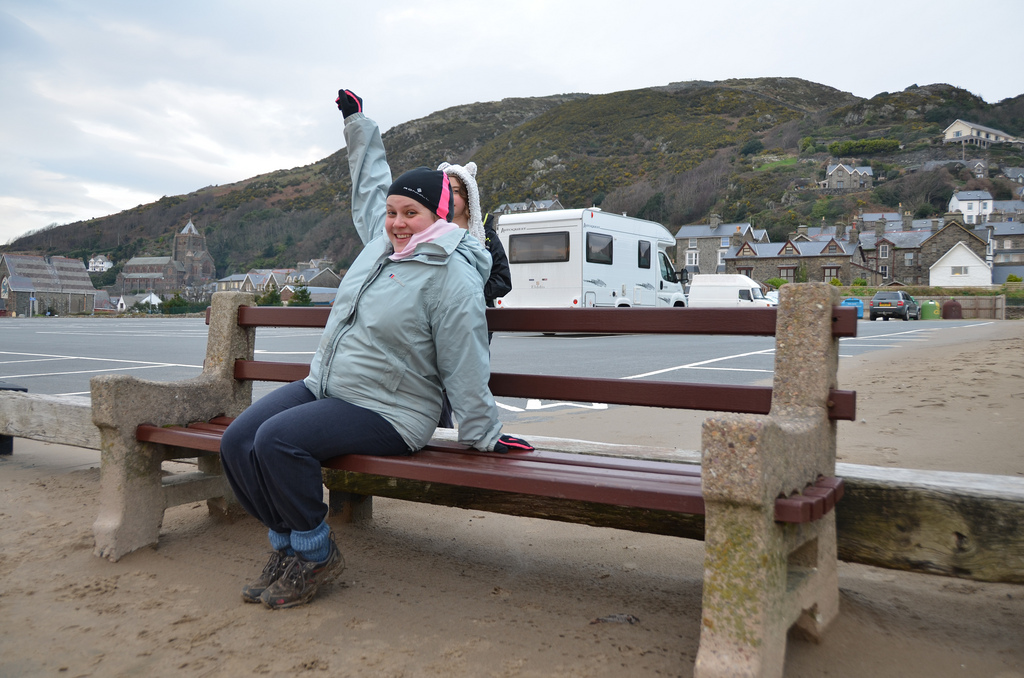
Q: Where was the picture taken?
A: It was taken at the parking lot.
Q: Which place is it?
A: It is a parking lot.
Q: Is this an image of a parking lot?
A: Yes, it is showing a parking lot.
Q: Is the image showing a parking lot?
A: Yes, it is showing a parking lot.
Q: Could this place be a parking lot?
A: Yes, it is a parking lot.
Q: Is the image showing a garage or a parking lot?
A: It is showing a parking lot.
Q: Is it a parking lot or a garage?
A: It is a parking lot.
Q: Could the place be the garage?
A: No, it is the parking lot.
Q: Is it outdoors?
A: Yes, it is outdoors.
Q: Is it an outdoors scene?
A: Yes, it is outdoors.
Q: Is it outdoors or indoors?
A: It is outdoors.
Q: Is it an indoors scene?
A: No, it is outdoors.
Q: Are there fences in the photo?
A: No, there are no fences.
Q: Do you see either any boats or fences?
A: No, there are no fences or boats.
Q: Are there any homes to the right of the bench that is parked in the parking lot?
A: Yes, there are homes to the right of the bench.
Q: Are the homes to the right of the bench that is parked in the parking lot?
A: Yes, the homes are to the right of the bench.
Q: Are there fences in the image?
A: No, there are no fences.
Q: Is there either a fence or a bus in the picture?
A: No, there are no fences or buses.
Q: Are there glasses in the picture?
A: No, there are no glasses.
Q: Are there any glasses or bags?
A: No, there are no glasses or bags.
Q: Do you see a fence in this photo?
A: No, there are no fences.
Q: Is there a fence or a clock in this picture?
A: No, there are no fences or clocks.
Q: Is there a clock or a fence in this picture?
A: No, there are no fences or clocks.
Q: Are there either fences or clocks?
A: No, there are no fences or clocks.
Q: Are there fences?
A: No, there are no fences.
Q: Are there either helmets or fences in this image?
A: No, there are no fences or helmets.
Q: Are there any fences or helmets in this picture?
A: No, there are no fences or helmets.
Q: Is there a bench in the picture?
A: Yes, there is a bench.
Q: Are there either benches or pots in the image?
A: Yes, there is a bench.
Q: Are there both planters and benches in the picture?
A: No, there is a bench but no planters.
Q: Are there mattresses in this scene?
A: No, there are no mattresses.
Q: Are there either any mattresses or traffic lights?
A: No, there are no mattresses or traffic lights.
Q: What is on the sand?
A: The bench is on the sand.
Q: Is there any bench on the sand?
A: Yes, there is a bench on the sand.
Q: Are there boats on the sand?
A: No, there is a bench on the sand.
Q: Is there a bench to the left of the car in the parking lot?
A: Yes, there is a bench to the left of the car.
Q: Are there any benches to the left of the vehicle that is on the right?
A: Yes, there is a bench to the left of the car.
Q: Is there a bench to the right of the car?
A: No, the bench is to the left of the car.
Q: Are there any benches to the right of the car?
A: No, the bench is to the left of the car.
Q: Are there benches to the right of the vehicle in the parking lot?
A: No, the bench is to the left of the car.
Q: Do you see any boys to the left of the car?
A: No, there is a bench to the left of the car.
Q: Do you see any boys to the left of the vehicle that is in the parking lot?
A: No, there is a bench to the left of the car.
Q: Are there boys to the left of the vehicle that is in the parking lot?
A: No, there is a bench to the left of the car.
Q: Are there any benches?
A: Yes, there is a bench.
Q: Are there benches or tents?
A: Yes, there is a bench.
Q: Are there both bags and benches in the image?
A: No, there is a bench but no bags.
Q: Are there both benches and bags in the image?
A: No, there is a bench but no bags.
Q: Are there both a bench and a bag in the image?
A: No, there is a bench but no bags.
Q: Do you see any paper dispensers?
A: No, there are no paper dispensers.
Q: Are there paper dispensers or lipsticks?
A: No, there are no paper dispensers or lipsticks.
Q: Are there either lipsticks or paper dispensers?
A: No, there are no paper dispensers or lipsticks.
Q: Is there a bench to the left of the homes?
A: Yes, there is a bench to the left of the homes.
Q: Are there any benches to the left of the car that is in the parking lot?
A: Yes, there is a bench to the left of the car.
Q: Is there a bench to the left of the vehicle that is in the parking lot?
A: Yes, there is a bench to the left of the car.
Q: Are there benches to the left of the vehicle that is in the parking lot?
A: Yes, there is a bench to the left of the car.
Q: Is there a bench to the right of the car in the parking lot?
A: No, the bench is to the left of the car.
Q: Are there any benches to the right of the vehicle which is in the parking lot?
A: No, the bench is to the left of the car.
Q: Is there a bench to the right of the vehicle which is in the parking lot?
A: No, the bench is to the left of the car.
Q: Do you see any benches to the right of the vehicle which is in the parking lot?
A: No, the bench is to the left of the car.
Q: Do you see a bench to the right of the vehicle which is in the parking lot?
A: No, the bench is to the left of the car.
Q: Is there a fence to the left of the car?
A: No, there is a bench to the left of the car.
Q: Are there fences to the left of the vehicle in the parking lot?
A: No, there is a bench to the left of the car.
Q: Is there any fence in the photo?
A: No, there are no fences.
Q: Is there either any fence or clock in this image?
A: No, there are no fences or clocks.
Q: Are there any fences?
A: No, there are no fences.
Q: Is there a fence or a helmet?
A: No, there are no fences or helmets.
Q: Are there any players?
A: No, there are no players.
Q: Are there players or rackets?
A: No, there are no players or rackets.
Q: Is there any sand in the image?
A: Yes, there is sand.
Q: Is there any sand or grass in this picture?
A: Yes, there is sand.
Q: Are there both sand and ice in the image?
A: No, there is sand but no ice.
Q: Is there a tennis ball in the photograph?
A: No, there are no tennis balls.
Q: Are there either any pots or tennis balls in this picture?
A: No, there are no tennis balls or pots.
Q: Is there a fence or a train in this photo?
A: No, there are no fences or trains.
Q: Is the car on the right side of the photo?
A: Yes, the car is on the right of the image.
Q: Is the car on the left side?
A: No, the car is on the right of the image.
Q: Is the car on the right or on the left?
A: The car is on the right of the image.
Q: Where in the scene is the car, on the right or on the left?
A: The car is on the right of the image.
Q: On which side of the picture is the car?
A: The car is on the right of the image.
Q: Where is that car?
A: The car is in the parking lot.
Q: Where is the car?
A: The car is in the parking lot.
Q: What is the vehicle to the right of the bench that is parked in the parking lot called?
A: The vehicle is a car.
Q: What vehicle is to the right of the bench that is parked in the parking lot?
A: The vehicle is a car.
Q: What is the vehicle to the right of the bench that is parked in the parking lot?
A: The vehicle is a car.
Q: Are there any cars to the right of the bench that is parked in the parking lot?
A: Yes, there is a car to the right of the bench.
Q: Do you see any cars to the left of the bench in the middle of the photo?
A: No, the car is to the right of the bench.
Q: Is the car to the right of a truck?
A: No, the car is to the right of the bench.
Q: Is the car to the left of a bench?
A: No, the car is to the right of a bench.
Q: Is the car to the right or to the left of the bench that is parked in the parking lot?
A: The car is to the right of the bench.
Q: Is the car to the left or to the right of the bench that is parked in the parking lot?
A: The car is to the right of the bench.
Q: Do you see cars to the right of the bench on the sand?
A: Yes, there is a car to the right of the bench.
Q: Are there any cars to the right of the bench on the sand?
A: Yes, there is a car to the right of the bench.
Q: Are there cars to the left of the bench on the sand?
A: No, the car is to the right of the bench.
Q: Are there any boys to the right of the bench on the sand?
A: No, there is a car to the right of the bench.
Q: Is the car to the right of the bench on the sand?
A: Yes, the car is to the right of the bench.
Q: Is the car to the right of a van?
A: No, the car is to the right of the bench.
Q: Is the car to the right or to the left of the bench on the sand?
A: The car is to the right of the bench.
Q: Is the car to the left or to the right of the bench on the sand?
A: The car is to the right of the bench.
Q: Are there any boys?
A: No, there are no boys.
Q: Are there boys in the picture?
A: No, there are no boys.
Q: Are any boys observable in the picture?
A: No, there are no boys.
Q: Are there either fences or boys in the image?
A: No, there are no boys or fences.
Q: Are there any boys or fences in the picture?
A: No, there are no boys or fences.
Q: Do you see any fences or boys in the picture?
A: No, there are no boys or fences.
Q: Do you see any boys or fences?
A: No, there are no boys or fences.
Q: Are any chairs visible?
A: No, there are no chairs.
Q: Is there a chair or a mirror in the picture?
A: No, there are no chairs or mirrors.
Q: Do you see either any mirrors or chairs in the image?
A: No, there are no chairs or mirrors.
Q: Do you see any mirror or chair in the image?
A: No, there are no chairs or mirrors.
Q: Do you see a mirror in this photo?
A: No, there are no mirrors.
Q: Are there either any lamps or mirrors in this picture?
A: No, there are no mirrors or lamps.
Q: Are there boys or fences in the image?
A: No, there are no fences or boys.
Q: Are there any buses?
A: No, there are no buses.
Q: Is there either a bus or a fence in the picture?
A: No, there are no buses or fences.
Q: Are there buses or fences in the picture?
A: No, there are no buses or fences.